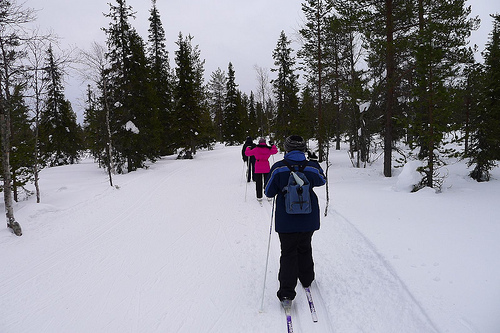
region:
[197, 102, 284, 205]
a skier wearing a pink parka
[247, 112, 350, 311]
A skier wearing a black and blue jacet with matching backpack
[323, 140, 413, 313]
ski tracks in the snow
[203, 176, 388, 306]
Warm black ski pants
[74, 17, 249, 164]
Many evergreen trees long the trail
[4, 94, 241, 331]
A snow covered ground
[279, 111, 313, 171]
Black knitted cap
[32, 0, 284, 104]
An overcast sky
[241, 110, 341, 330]
three people cross country skiing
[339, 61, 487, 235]
A small snow drift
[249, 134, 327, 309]
Snow skier dressed in blue snow suit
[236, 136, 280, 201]
Snow skier dressed in pink snow jacket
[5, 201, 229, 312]
patch of virgin snow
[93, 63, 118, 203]
dead pine tree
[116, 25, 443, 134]
beautiful green pine trees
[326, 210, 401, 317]
tracks made in the snow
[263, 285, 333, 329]
two snow skis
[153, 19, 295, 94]
beautiful winter sky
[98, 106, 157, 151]
snow on boughs of pine tree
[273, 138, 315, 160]
black snow hat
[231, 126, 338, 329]
People out skiing on snow.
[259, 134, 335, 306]
Person wearing a blue jacket.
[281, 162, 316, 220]
Person carrying a blue backpack.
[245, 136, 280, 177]
Person wearing a pink jacket.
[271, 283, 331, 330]
Rear of skis attached to person's feet.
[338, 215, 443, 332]
Ski tracks in snow.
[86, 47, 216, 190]
Pine trees growing along ski path.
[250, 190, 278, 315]
Person holding a ski pole.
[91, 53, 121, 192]
Bare tree growing along ski path.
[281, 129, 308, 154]
Person wearing gray cap.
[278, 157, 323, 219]
a small blue backpack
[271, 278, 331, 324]
purple and white skis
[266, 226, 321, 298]
pair of black skipants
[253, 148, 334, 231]
a blue striped ski jacket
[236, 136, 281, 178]
bright pink snow jacket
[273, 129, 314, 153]
a black knit hat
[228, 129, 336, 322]
a few people cross country skiing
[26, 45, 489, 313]
snowy winter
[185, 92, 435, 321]
ski path through trees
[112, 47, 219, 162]
group of evergreen trees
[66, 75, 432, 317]
A group of people cross-country skiing.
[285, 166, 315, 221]
The person has a backpack on.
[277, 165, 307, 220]
The backpack is blue.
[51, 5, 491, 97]
The sky is overcast.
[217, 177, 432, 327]
Tracks in the snow.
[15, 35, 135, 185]
Some trees have lost their leaves.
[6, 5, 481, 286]
The people are in a forest.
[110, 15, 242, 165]
Evergreen trees.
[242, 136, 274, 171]
The person is wearing a pink coat.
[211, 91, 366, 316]
The people are holding on to ski poles.